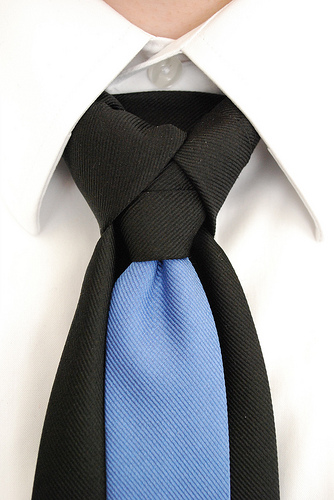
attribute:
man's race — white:
[107, 0, 224, 54]